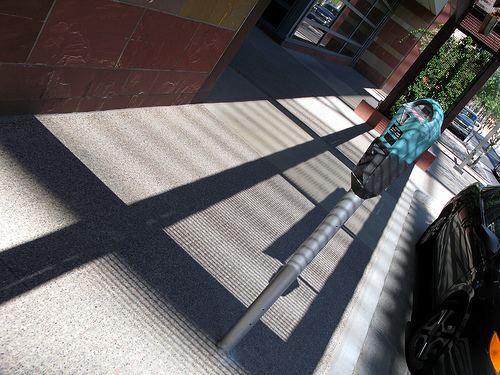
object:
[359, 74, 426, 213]
meter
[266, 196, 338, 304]
pole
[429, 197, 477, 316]
car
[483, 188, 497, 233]
window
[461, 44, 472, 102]
column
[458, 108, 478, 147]
truck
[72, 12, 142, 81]
wall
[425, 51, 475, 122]
tree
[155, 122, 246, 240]
sidewalk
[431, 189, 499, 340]
vehicle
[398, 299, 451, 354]
tire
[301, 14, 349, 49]
windows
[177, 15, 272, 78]
building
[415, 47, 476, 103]
plant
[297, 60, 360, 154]
floor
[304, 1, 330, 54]
partition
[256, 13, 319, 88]
entrance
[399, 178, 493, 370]
vehicle